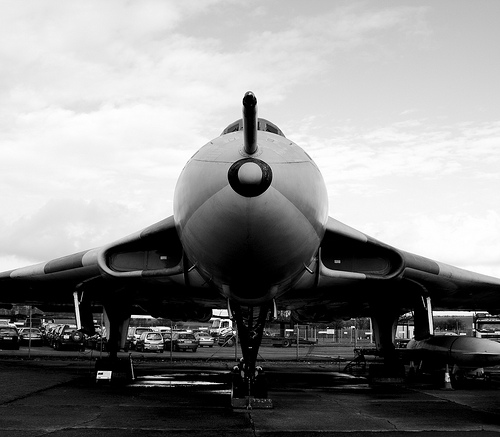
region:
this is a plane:
[0, 88, 498, 378]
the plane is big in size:
[5, 86, 497, 405]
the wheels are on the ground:
[217, 355, 279, 410]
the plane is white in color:
[0, 107, 499, 399]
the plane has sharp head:
[198, 98, 290, 228]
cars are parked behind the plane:
[130, 327, 222, 350]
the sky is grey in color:
[2, 1, 497, 84]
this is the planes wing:
[1, 247, 98, 308]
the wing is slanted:
[1, 212, 176, 309]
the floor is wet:
[135, 366, 217, 401]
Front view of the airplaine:
[0, 93, 496, 433]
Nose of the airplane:
[227, 156, 268, 196]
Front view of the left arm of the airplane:
[277, 223, 497, 341]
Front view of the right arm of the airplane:
[0, 218, 230, 349]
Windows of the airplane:
[220, 118, 280, 133]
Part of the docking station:
[0, 335, 496, 432]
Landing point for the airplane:
[70, 366, 380, 391]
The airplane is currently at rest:
[3, 90, 498, 377]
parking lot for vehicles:
[1, 310, 496, 356]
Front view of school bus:
[472, 309, 499, 343]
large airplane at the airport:
[0, 84, 499, 402]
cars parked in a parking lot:
[1, 313, 236, 357]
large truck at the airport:
[468, 308, 499, 354]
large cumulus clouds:
[1, 1, 163, 213]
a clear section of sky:
[356, 63, 499, 105]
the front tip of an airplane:
[235, 88, 269, 160]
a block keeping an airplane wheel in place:
[90, 366, 117, 381]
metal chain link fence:
[275, 326, 357, 361]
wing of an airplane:
[1, 213, 183, 308]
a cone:
[438, 362, 455, 394]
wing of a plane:
[17, 247, 200, 347]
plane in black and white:
[40, 120, 454, 395]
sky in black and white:
[25, 110, 112, 200]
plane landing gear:
[67, 327, 453, 419]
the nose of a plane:
[181, 147, 347, 237]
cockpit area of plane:
[206, 110, 327, 155]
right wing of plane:
[309, 202, 488, 356]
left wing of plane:
[12, 212, 170, 331]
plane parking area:
[280, 360, 408, 433]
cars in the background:
[142, 325, 197, 353]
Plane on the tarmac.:
[30, 58, 495, 321]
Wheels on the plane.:
[66, 305, 498, 402]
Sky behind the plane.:
[50, 37, 473, 317]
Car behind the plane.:
[81, 304, 211, 357]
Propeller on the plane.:
[215, 128, 315, 233]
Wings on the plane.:
[13, 242, 251, 334]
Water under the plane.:
[29, 369, 265, 414]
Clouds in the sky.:
[47, 145, 167, 230]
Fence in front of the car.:
[144, 324, 227, 364]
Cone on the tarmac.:
[419, 357, 482, 407]